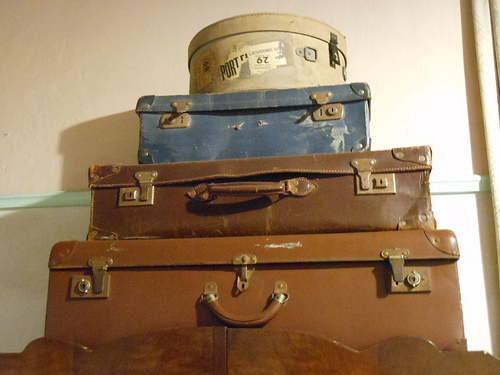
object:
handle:
[197, 262, 304, 337]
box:
[186, 10, 349, 93]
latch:
[309, 91, 345, 120]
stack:
[44, 12, 468, 352]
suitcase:
[85, 145, 435, 241]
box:
[42, 223, 467, 350]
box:
[133, 80, 374, 165]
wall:
[0, 0, 500, 355]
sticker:
[216, 40, 287, 84]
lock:
[384, 251, 434, 293]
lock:
[115, 171, 155, 206]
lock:
[60, 256, 112, 300]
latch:
[349, 157, 396, 194]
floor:
[0, 340, 484, 360]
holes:
[235, 119, 267, 131]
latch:
[229, 252, 256, 293]